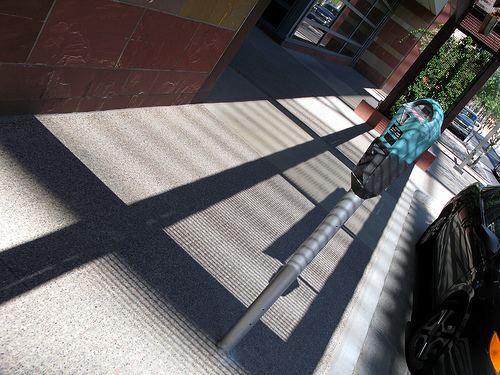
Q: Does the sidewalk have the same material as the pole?
A: No, the sidewalk is made of concrete and the pole is made of metal.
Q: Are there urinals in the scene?
A: No, there are no urinals.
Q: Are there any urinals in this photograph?
A: No, there are no urinals.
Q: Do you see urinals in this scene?
A: No, there are no urinals.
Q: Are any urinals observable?
A: No, there are no urinals.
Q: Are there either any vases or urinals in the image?
A: No, there are no urinals or vases.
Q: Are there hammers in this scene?
A: No, there are no hammers.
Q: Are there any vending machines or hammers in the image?
A: No, there are no hammers or vending machines.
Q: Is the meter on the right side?
A: Yes, the meter is on the right of the image.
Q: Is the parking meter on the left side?
A: No, the parking meter is on the right of the image.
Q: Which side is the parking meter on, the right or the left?
A: The parking meter is on the right of the image.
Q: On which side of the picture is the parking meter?
A: The parking meter is on the right of the image.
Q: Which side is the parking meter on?
A: The parking meter is on the right of the image.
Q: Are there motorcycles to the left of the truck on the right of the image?
A: No, there is a parking meter to the left of the truck.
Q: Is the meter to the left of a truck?
A: Yes, the meter is to the left of a truck.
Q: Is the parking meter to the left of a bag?
A: No, the parking meter is to the left of a truck.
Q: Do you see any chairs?
A: No, there are no chairs.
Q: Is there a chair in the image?
A: No, there are no chairs.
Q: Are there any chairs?
A: No, there are no chairs.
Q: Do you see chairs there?
A: No, there are no chairs.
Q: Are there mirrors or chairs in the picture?
A: No, there are no chairs or mirrors.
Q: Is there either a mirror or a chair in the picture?
A: No, there are no chairs or mirrors.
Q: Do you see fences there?
A: No, there are no fences.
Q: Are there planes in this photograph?
A: No, there are no planes.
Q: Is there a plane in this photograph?
A: No, there are no airplanes.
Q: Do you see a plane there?
A: No, there are no airplanes.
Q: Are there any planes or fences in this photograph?
A: No, there are no planes or fences.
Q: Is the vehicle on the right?
A: Yes, the vehicle is on the right of the image.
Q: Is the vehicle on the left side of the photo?
A: No, the vehicle is on the right of the image.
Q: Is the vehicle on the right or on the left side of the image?
A: The vehicle is on the right of the image.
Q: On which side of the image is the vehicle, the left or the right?
A: The vehicle is on the right of the image.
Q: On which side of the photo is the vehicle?
A: The vehicle is on the right of the image.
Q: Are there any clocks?
A: No, there are no clocks.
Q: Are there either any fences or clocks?
A: No, there are no clocks or fences.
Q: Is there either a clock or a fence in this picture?
A: No, there are no clocks or fences.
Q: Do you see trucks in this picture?
A: Yes, there is a truck.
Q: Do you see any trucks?
A: Yes, there is a truck.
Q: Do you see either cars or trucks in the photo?
A: Yes, there is a truck.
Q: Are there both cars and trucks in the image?
A: Yes, there are both a truck and cars.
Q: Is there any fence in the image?
A: No, there are no fences.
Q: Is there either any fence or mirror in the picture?
A: No, there are no fences or mirrors.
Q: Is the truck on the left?
A: No, the truck is on the right of the image.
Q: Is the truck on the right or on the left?
A: The truck is on the right of the image.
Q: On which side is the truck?
A: The truck is on the right of the image.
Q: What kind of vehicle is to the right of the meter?
A: The vehicle is a truck.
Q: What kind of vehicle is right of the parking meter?
A: The vehicle is a truck.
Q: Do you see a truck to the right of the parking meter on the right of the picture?
A: Yes, there is a truck to the right of the parking meter.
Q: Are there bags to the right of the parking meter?
A: No, there is a truck to the right of the parking meter.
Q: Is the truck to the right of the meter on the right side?
A: Yes, the truck is to the right of the meter.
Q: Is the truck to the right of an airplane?
A: No, the truck is to the right of the meter.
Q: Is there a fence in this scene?
A: No, there are no fences.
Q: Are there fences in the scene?
A: No, there are no fences.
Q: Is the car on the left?
A: No, the car is on the right of the image.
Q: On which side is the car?
A: The car is on the right of the image.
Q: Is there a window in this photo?
A: Yes, there is a window.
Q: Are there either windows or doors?
A: Yes, there is a window.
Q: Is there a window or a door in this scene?
A: Yes, there is a window.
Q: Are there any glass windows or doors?
A: Yes, there is a glass window.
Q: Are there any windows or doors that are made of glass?
A: Yes, the window is made of glass.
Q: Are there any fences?
A: No, there are no fences.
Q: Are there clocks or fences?
A: No, there are no fences or clocks.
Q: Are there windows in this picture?
A: Yes, there are windows.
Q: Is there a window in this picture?
A: Yes, there are windows.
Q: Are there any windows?
A: Yes, there are windows.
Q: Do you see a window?
A: Yes, there are windows.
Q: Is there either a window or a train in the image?
A: Yes, there are windows.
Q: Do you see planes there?
A: No, there are no planes.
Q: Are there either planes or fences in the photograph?
A: No, there are no planes or fences.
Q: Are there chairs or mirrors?
A: No, there are no chairs or mirrors.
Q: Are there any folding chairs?
A: No, there are no folding chairs.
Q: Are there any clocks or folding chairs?
A: No, there are no folding chairs or clocks.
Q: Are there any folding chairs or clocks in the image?
A: No, there are no folding chairs or clocks.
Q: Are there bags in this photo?
A: No, there are no bags.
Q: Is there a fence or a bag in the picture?
A: No, there are no bags or fences.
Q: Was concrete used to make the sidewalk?
A: Yes, the sidewalk is made of concrete.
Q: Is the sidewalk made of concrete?
A: Yes, the sidewalk is made of concrete.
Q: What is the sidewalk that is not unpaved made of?
A: The sidewalk is made of cement.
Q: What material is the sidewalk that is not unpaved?
A: The sidewalk is made of cement.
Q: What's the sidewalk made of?
A: The sidewalk is made of concrete.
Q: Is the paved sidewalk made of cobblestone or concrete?
A: The sidewalk is made of concrete.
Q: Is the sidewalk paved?
A: Yes, the sidewalk is paved.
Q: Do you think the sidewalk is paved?
A: Yes, the sidewalk is paved.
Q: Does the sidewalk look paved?
A: Yes, the sidewalk is paved.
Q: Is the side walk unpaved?
A: No, the side walk is paved.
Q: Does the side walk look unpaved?
A: No, the side walk is paved.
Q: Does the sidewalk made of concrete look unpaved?
A: No, the sidewalk is paved.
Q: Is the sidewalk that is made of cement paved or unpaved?
A: The side walk is paved.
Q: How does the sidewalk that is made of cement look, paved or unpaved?
A: The side walk is paved.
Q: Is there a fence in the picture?
A: No, there are no fences.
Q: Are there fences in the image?
A: No, there are no fences.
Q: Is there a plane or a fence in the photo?
A: No, there are no fences or airplanes.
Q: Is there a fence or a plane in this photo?
A: No, there are no fences or airplanes.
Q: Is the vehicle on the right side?
A: Yes, the vehicle is on the right of the image.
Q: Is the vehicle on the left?
A: No, the vehicle is on the right of the image.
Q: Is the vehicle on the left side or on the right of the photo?
A: The vehicle is on the right of the image.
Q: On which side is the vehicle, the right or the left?
A: The vehicle is on the right of the image.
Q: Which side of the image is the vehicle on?
A: The vehicle is on the right of the image.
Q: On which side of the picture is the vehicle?
A: The vehicle is on the right of the image.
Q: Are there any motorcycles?
A: No, there are no motorcycles.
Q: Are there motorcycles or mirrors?
A: No, there are no motorcycles or mirrors.